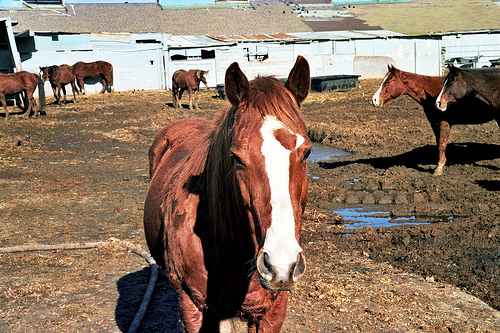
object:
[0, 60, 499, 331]
horses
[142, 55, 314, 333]
horse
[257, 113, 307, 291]
white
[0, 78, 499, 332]
ground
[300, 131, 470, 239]
water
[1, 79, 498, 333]
mud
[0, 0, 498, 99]
stables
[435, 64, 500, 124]
horse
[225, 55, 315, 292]
head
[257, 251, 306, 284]
nose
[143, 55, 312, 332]
alone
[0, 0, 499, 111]
background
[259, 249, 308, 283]
nostrils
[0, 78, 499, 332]
dirt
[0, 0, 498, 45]
roof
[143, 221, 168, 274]
stomach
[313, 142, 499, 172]
shade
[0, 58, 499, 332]
standing